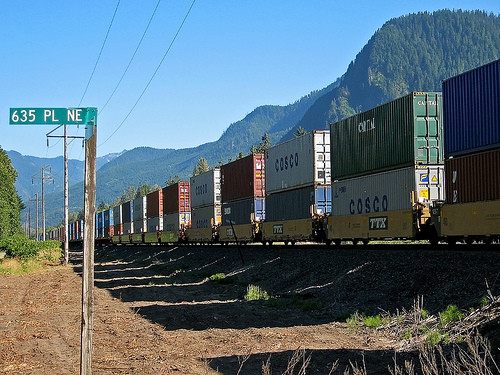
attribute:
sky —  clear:
[3, 4, 498, 158]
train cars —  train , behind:
[41, 56, 498, 252]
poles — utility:
[0, 175, 66, 245]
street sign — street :
[6, 106, 98, 125]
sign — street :
[10, 107, 97, 124]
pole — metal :
[77, 126, 97, 373]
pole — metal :
[80, 107, 97, 372]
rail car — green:
[331, 97, 449, 167]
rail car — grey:
[327, 176, 438, 208]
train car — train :
[444, 60, 499, 237]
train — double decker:
[174, 90, 441, 258]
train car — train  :
[433, 49, 497, 239]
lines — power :
[70, 16, 175, 123]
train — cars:
[91, 84, 457, 304]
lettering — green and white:
[8, 105, 83, 129]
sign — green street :
[6, 104, 96, 127]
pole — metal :
[81, 132, 97, 374]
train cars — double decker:
[260, 120, 332, 246]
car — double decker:
[435, 62, 497, 247]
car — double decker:
[319, 83, 442, 248]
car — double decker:
[260, 120, 329, 240]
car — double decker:
[220, 143, 260, 243]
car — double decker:
[184, 160, 216, 245]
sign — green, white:
[9, 103, 90, 132]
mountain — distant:
[265, 8, 498, 144]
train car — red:
[217, 153, 267, 202]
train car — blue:
[220, 196, 267, 229]